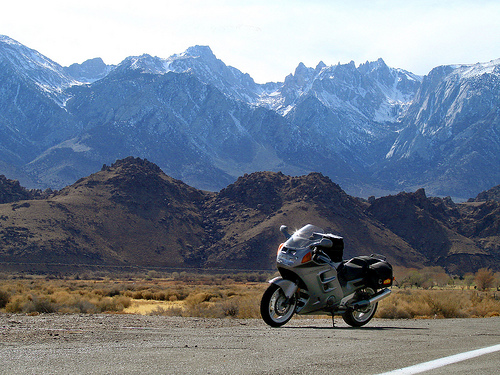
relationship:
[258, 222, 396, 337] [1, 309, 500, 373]
motorcycle on road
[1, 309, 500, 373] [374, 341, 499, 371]
road has line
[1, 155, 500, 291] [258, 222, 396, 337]
hills behind motorcycle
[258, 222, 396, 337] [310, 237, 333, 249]
motorcycle has mirrors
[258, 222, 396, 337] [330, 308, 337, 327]
motorcycle has kickstand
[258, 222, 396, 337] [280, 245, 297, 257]
motorcycle has lights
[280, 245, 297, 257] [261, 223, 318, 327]
lights on front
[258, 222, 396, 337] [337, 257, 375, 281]
motorcycle has seat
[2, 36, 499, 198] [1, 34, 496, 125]
mountains have snow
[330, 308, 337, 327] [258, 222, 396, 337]
kickstand holds motorcycle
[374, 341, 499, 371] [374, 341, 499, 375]
line marks line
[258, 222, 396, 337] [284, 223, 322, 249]
motorcycle has windshield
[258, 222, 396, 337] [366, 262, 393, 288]
motorcycle has container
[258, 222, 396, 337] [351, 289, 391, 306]
motorcycle has pipe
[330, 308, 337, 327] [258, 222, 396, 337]
kickstand on motorcycle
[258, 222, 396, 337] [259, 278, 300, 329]
motorcycle has wheels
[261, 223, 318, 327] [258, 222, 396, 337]
front of motorcycle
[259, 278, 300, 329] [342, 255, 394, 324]
wheels on rear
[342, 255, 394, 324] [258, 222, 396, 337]
rear of motorcycle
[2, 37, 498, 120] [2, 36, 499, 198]
tops of mountains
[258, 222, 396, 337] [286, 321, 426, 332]
motorcycle has shadow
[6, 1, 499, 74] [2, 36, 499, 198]
sky above mountains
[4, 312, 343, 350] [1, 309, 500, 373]
side of road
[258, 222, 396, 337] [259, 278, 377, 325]
motorcycle has wheels